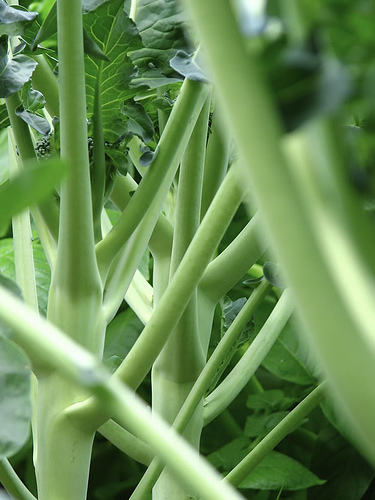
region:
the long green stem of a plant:
[95, 175, 159, 253]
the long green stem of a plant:
[3, 128, 48, 378]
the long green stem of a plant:
[205, 282, 289, 414]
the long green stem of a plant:
[2, 290, 234, 497]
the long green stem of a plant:
[219, 374, 327, 487]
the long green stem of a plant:
[90, 81, 109, 242]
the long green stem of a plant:
[2, 454, 34, 497]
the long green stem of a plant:
[189, 2, 373, 448]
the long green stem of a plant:
[198, 209, 269, 297]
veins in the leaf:
[83, 17, 125, 122]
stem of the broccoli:
[18, 369, 120, 470]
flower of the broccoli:
[34, 128, 66, 175]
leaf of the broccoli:
[253, 352, 279, 417]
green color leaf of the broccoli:
[90, 6, 145, 112]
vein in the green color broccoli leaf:
[106, 31, 149, 101]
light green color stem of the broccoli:
[42, 429, 72, 498]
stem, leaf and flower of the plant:
[37, 148, 340, 388]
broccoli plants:
[9, 170, 308, 497]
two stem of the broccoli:
[37, 249, 219, 417]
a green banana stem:
[137, 274, 190, 358]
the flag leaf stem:
[90, 120, 105, 204]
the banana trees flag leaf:
[84, 3, 146, 141]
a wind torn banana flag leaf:
[125, 49, 181, 112]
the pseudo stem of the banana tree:
[28, 377, 91, 499]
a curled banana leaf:
[14, 88, 53, 140]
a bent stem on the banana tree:
[49, 252, 104, 325]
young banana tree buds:
[33, 136, 55, 159]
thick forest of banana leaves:
[250, 0, 373, 230]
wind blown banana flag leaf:
[125, 47, 186, 118]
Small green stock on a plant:
[54, 24, 114, 289]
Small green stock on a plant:
[3, 139, 34, 300]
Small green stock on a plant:
[182, 120, 197, 262]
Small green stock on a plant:
[78, 420, 245, 497]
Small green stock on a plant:
[231, 158, 374, 359]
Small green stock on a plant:
[168, 164, 231, 356]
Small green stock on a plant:
[101, 107, 181, 281]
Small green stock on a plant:
[6, 375, 151, 498]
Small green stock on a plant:
[236, 371, 340, 491]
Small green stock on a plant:
[105, 36, 211, 204]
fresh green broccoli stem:
[3, 276, 148, 441]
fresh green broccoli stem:
[211, 284, 284, 413]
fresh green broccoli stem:
[114, 389, 208, 494]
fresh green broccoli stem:
[207, 47, 343, 235]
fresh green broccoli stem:
[51, 83, 101, 372]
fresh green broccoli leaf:
[76, 6, 142, 160]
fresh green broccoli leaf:
[218, 432, 355, 499]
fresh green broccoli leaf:
[210, 290, 256, 363]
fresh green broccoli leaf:
[128, 2, 196, 94]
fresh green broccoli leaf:
[1, 3, 53, 137]